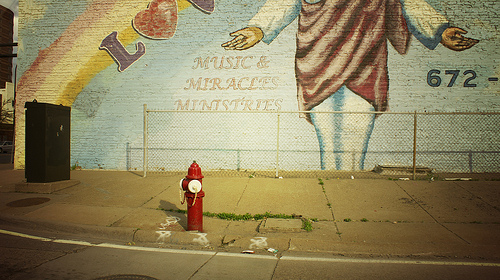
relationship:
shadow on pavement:
[155, 195, 187, 231] [3, 167, 498, 277]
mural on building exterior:
[9, 0, 499, 179] [12, 0, 497, 170]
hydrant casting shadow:
[178, 160, 205, 235] [155, 195, 187, 231]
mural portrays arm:
[9, 0, 499, 179] [386, 0, 450, 59]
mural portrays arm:
[9, 0, 499, 179] [245, 1, 299, 46]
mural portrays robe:
[29, 13, 494, 170] [299, 0, 396, 119]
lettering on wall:
[173, 49, 282, 115] [7, 2, 484, 175]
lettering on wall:
[172, 97, 282, 114] [7, 2, 484, 175]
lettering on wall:
[173, 49, 282, 115] [225, 22, 323, 110]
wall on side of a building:
[7, 2, 484, 175] [15, 10, 436, 278]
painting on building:
[15, 0, 500, 168] [9, 0, 498, 173]